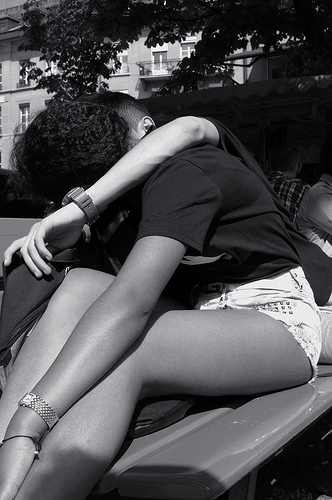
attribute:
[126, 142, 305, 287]
shirt — black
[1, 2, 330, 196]
building — tan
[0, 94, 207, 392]
person — sitting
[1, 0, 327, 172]
building — tan